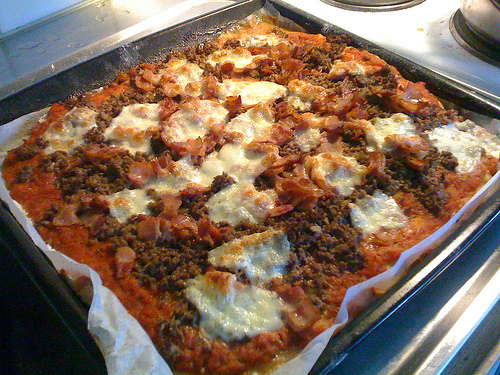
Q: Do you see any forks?
A: No, there are no forks.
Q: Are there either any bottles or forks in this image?
A: No, there are no forks or bottles.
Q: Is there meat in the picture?
A: Yes, there is meat.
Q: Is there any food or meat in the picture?
A: Yes, there is meat.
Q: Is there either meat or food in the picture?
A: Yes, there is meat.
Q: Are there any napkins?
A: No, there are no napkins.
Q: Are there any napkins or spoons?
A: No, there are no napkins or spoons.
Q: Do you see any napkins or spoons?
A: No, there are no napkins or spoons.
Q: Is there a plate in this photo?
A: Yes, there is a plate.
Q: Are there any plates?
A: Yes, there is a plate.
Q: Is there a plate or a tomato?
A: Yes, there is a plate.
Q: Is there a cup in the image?
A: No, there are no cups.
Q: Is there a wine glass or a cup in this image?
A: No, there are no cups or wine glasses.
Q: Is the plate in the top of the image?
A: Yes, the plate is in the top of the image.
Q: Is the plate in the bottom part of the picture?
A: No, the plate is in the top of the image.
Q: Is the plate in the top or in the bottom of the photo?
A: The plate is in the top of the image.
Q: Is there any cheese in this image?
A: Yes, there is cheese.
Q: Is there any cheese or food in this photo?
A: Yes, there is cheese.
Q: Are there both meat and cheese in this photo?
A: Yes, there are both cheese and meat.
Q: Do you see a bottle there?
A: No, there are no bottles.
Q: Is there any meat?
A: Yes, there is meat.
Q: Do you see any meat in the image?
A: Yes, there is meat.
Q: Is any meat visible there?
A: Yes, there is meat.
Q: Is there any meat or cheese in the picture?
A: Yes, there is meat.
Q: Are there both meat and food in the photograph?
A: Yes, there are both meat and food.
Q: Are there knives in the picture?
A: No, there are no knives.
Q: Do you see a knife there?
A: No, there are no knives.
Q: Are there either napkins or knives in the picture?
A: No, there are no knives or napkins.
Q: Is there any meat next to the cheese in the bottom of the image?
A: Yes, there is meat next to the cheese.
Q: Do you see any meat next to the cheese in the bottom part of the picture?
A: Yes, there is meat next to the cheese.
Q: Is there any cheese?
A: Yes, there is cheese.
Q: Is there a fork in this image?
A: No, there are no forks.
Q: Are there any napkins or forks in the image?
A: No, there are no forks or napkins.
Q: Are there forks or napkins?
A: No, there are no forks or napkins.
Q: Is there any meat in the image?
A: Yes, there is meat.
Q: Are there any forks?
A: No, there are no forks.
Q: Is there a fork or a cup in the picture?
A: No, there are no forks or cups.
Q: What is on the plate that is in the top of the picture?
A: The meat is on the plate.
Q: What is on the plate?
A: The meat is on the plate.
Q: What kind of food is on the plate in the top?
A: The food is meat.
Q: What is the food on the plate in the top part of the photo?
A: The food is meat.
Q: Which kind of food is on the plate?
A: The food is meat.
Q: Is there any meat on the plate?
A: Yes, there is meat on the plate.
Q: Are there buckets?
A: No, there are no buckets.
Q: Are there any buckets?
A: No, there are no buckets.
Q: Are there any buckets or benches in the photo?
A: No, there are no buckets or benches.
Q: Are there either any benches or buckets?
A: No, there are no buckets or benches.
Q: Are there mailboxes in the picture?
A: No, there are no mailboxes.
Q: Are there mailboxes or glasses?
A: No, there are no mailboxes or glasses.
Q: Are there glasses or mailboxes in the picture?
A: No, there are no mailboxes or glasses.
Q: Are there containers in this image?
A: No, there are no containers.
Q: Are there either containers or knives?
A: No, there are no containers or knives.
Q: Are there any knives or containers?
A: No, there are no containers or knives.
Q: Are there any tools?
A: No, there are no tools.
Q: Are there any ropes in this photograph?
A: No, there are no ropes.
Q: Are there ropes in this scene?
A: No, there are no ropes.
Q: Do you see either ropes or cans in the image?
A: No, there are no ropes or cans.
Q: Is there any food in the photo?
A: Yes, there is food.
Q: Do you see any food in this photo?
A: Yes, there is food.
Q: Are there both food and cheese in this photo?
A: Yes, there are both food and cheese.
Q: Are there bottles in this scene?
A: No, there are no bottles.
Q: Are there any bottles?
A: No, there are no bottles.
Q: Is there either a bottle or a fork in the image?
A: No, there are no bottles or forks.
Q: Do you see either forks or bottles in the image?
A: No, there are no bottles or forks.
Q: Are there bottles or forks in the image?
A: No, there are no bottles or forks.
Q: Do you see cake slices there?
A: No, there are no cake slices.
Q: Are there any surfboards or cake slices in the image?
A: No, there are no cake slices or surfboards.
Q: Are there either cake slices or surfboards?
A: No, there are no cake slices or surfboards.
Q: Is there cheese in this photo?
A: Yes, there is cheese.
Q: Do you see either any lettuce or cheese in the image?
A: Yes, there is cheese.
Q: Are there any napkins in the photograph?
A: No, there are no napkins.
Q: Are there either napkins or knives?
A: No, there are no napkins or knives.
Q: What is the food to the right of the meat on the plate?
A: The food is cheese.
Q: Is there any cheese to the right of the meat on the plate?
A: Yes, there is cheese to the right of the meat.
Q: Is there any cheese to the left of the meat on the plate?
A: No, the cheese is to the right of the meat.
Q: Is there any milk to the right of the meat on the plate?
A: No, there is cheese to the right of the meat.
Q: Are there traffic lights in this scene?
A: No, there are no traffic lights.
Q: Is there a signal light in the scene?
A: No, there are no traffic lights.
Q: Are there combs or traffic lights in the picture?
A: No, there are no traffic lights or combs.